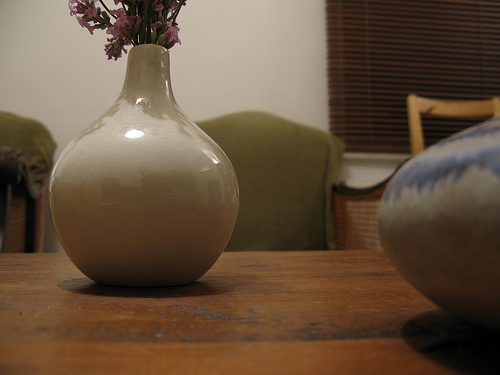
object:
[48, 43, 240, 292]
vase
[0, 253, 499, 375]
table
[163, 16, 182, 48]
flowers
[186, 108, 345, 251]
chair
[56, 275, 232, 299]
shadow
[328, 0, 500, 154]
blinds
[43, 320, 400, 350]
grooves